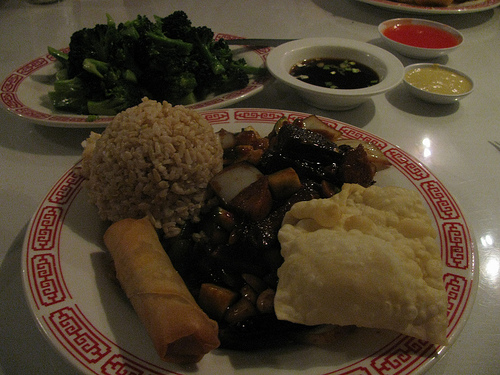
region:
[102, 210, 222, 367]
Crispy brown egg roll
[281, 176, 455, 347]
Puffy and crispy wonton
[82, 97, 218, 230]
Ball of sticky brown rice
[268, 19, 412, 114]
Bowl of dark brown soy sauce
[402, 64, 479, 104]
Bowl of yellow sauce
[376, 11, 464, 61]
Bowl of reddish looking sauce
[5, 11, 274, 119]
Plate filled with green broccoli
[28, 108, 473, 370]
Plate filled with Asian style food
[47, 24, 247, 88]
Green brocolli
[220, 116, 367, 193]
Asian meat dish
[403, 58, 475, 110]
small bowl of chinese mustard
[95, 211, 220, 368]
egg roll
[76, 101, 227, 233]
scoop of brown rice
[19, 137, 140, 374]
dinner plate with red pattern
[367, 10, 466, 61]
bowl of sweet and sour sauce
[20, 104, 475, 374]
plate of chinese food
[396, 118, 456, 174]
reflection of light on table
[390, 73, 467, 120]
shadow of small bowl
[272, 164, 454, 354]
fried wonton wrapper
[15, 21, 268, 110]
plate of broccoli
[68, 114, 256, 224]
Rice on a plate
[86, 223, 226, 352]
Egg roll on a plate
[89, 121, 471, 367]
Dinner on a plate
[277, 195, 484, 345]
Chip on a white and red plate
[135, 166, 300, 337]
Food on a plate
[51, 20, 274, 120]
Broccoli on a plate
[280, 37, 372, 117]
Soup in a bowel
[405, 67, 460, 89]
Yellow sauce in a bowel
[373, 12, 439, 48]
Orange sauce in a bowel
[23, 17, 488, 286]
Table with food on it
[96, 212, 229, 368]
spring roll on a plate.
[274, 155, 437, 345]
fried dumpling on a plate.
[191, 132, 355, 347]
A Asian meat and veggie dish.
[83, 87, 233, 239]
A round ball of rice.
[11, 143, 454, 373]
Asian food on a red and white plate.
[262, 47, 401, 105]
A dipping sauce in a white dish.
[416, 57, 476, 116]
A yellow dipping sauce in a white dish.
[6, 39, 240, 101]
Broccoli on a red and white plate.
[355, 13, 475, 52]
Pink dipping sauce in white dish.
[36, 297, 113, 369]
Red and white Asian design.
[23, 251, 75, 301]
red design on white plate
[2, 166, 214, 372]
large white plate with design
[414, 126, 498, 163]
reflection of light on the table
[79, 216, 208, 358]
long brown eggroll on plate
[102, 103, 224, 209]
small cluster of fried rice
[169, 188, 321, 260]
shiny red spare rib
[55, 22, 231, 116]
plate full of green broccoli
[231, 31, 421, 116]
white saucer with brown sauce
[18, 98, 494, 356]
red and white plate